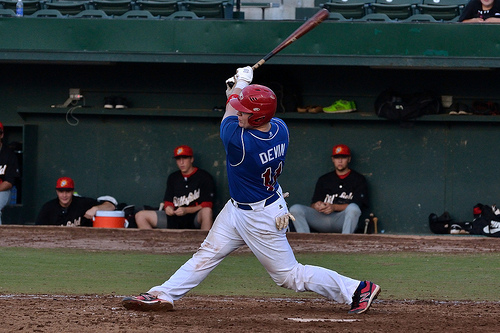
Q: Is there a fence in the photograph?
A: No, there are no fences.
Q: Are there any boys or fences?
A: No, there are no fences or boys.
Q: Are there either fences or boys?
A: No, there are no fences or boys.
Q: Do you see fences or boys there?
A: No, there are no fences or boys.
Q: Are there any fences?
A: No, there are no fences.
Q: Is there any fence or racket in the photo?
A: No, there are no fences or rackets.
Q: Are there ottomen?
A: No, there are no ottomen.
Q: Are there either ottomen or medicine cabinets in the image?
A: No, there are no ottomen or medicine cabinets.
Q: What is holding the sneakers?
A: The shelf is holding the sneakers.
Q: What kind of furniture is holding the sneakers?
A: The piece of furniture is a shelf.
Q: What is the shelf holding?
A: The shelf is holding the sneakers.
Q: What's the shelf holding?
A: The shelf is holding the sneakers.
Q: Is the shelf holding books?
A: No, the shelf is holding the sneakers.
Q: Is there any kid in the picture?
A: No, there are no children.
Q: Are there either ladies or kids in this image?
A: No, there are no kids or ladies.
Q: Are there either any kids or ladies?
A: No, there are no kids or ladies.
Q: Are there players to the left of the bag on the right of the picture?
A: Yes, there is a player to the left of the bag.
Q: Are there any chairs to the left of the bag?
A: No, there is a player to the left of the bag.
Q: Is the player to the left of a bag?
A: Yes, the player is to the left of a bag.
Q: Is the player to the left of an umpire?
A: No, the player is to the left of a bag.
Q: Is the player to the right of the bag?
A: No, the player is to the left of the bag.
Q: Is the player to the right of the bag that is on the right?
A: No, the player is to the left of the bag.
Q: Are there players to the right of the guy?
A: Yes, there is a player to the right of the guy.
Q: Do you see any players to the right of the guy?
A: Yes, there is a player to the right of the guy.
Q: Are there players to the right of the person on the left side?
A: Yes, there is a player to the right of the guy.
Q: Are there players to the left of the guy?
A: No, the player is to the right of the guy.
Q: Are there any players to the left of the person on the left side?
A: No, the player is to the right of the guy.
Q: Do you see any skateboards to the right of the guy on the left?
A: No, there is a player to the right of the guy.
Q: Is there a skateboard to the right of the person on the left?
A: No, there is a player to the right of the guy.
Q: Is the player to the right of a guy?
A: Yes, the player is to the right of a guy.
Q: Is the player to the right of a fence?
A: No, the player is to the right of a guy.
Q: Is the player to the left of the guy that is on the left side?
A: No, the player is to the right of the guy.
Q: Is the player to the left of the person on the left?
A: No, the player is to the right of the guy.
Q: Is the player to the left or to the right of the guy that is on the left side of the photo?
A: The player is to the right of the guy.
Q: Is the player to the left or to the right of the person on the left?
A: The player is to the right of the guy.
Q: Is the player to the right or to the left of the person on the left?
A: The player is to the right of the guy.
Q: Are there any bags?
A: Yes, there is a bag.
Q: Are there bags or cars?
A: Yes, there is a bag.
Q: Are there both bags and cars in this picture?
A: No, there is a bag but no cars.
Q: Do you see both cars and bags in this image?
A: No, there is a bag but no cars.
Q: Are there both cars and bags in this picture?
A: No, there is a bag but no cars.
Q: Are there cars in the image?
A: No, there are no cars.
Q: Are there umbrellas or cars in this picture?
A: No, there are no cars or umbrellas.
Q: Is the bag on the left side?
A: No, the bag is on the right of the image.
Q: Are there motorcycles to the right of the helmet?
A: No, there is a bag to the right of the helmet.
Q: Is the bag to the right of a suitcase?
A: No, the bag is to the right of the helmet.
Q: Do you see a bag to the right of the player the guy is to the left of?
A: Yes, there is a bag to the right of the player.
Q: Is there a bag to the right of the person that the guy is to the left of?
A: Yes, there is a bag to the right of the player.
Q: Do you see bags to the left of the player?
A: No, the bag is to the right of the player.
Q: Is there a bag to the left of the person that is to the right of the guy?
A: No, the bag is to the right of the player.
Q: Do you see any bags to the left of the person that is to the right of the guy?
A: No, the bag is to the right of the player.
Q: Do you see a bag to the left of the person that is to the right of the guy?
A: No, the bag is to the right of the player.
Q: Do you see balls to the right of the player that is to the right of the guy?
A: No, there is a bag to the right of the player.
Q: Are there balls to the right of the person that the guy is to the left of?
A: No, there is a bag to the right of the player.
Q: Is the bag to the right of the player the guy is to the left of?
A: Yes, the bag is to the right of the player.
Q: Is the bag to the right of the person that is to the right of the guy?
A: Yes, the bag is to the right of the player.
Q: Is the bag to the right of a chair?
A: No, the bag is to the right of the player.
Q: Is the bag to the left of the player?
A: No, the bag is to the right of the player.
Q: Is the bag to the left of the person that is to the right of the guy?
A: No, the bag is to the right of the player.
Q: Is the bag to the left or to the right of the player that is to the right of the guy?
A: The bag is to the right of the player.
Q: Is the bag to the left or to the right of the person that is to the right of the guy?
A: The bag is to the right of the player.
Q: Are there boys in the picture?
A: No, there are no boys.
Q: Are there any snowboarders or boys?
A: No, there are no boys or snowboarders.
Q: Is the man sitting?
A: Yes, the man is sitting.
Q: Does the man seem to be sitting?
A: Yes, the man is sitting.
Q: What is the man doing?
A: The man is sitting.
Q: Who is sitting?
A: The man is sitting.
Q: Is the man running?
A: No, the man is sitting.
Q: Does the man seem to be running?
A: No, the man is sitting.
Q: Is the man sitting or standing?
A: The man is sitting.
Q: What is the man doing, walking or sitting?
A: The man is sitting.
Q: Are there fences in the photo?
A: No, there are no fences.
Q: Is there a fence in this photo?
A: No, there are no fences.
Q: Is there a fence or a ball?
A: No, there are no fences or balls.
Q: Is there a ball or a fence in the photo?
A: No, there are no fences or balls.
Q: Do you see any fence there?
A: No, there are no fences.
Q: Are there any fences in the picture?
A: No, there are no fences.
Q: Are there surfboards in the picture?
A: No, there are no surfboards.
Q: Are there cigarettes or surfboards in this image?
A: No, there are no surfboards or cigarettes.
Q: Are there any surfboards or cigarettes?
A: No, there are no surfboards or cigarettes.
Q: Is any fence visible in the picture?
A: No, there are no fences.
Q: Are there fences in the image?
A: No, there are no fences.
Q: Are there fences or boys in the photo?
A: No, there are no fences or boys.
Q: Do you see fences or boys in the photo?
A: No, there are no fences or boys.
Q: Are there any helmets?
A: Yes, there is a helmet.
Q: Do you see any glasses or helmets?
A: Yes, there is a helmet.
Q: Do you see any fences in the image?
A: No, there are no fences.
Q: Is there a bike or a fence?
A: No, there are no fences or bikes.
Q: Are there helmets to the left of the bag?
A: Yes, there is a helmet to the left of the bag.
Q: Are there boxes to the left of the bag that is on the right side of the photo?
A: No, there is a helmet to the left of the bag.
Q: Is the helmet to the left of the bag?
A: Yes, the helmet is to the left of the bag.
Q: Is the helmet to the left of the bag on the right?
A: Yes, the helmet is to the left of the bag.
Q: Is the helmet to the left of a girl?
A: No, the helmet is to the left of the bag.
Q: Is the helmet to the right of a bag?
A: No, the helmet is to the left of a bag.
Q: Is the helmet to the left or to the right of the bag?
A: The helmet is to the left of the bag.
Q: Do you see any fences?
A: No, there are no fences.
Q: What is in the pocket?
A: The glove is in the pocket.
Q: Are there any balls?
A: No, there are no balls.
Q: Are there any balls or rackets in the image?
A: No, there are no balls or rackets.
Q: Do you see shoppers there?
A: No, there are no shoppers.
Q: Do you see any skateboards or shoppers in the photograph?
A: No, there are no shoppers or skateboards.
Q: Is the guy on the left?
A: Yes, the guy is on the left of the image.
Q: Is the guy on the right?
A: No, the guy is on the left of the image.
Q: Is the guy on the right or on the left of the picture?
A: The guy is on the left of the image.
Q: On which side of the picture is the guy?
A: The guy is on the left of the image.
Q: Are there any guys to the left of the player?
A: Yes, there is a guy to the left of the player.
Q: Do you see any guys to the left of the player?
A: Yes, there is a guy to the left of the player.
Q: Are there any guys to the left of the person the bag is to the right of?
A: Yes, there is a guy to the left of the player.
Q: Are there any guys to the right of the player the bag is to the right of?
A: No, the guy is to the left of the player.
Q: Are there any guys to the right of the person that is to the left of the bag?
A: No, the guy is to the left of the player.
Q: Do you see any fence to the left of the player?
A: No, there is a guy to the left of the player.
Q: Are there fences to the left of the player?
A: No, there is a guy to the left of the player.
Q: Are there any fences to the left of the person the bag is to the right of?
A: No, there is a guy to the left of the player.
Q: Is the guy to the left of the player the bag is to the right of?
A: Yes, the guy is to the left of the player.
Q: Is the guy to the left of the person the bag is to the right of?
A: Yes, the guy is to the left of the player.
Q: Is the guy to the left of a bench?
A: No, the guy is to the left of the player.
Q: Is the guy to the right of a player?
A: No, the guy is to the left of a player.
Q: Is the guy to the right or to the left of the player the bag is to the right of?
A: The guy is to the left of the player.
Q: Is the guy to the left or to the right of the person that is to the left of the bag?
A: The guy is to the left of the player.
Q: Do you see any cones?
A: No, there are no cones.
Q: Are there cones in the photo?
A: No, there are no cones.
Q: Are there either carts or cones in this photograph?
A: No, there are no cones or carts.